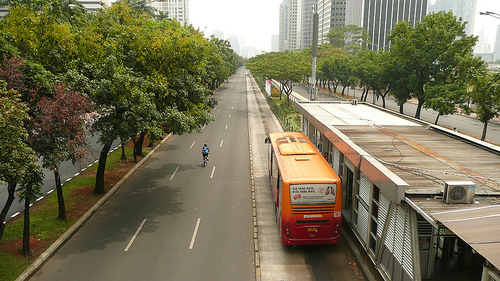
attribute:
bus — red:
[262, 127, 347, 252]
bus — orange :
[216, 121, 400, 233]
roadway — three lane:
[20, 51, 255, 279]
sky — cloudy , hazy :
[190, 3, 280, 38]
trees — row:
[232, 8, 487, 103]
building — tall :
[277, 0, 297, 51]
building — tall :
[312, 0, 362, 47]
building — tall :
[362, 0, 428, 51]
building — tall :
[432, 0, 476, 45]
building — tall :
[295, 0, 313, 48]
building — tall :
[278, 0, 293, 51]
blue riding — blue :
[201, 147, 210, 155]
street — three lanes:
[40, 69, 262, 273]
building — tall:
[275, 0, 300, 55]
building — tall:
[294, 0, 317, 50]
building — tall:
[313, 0, 345, 47]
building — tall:
[341, 0, 428, 56]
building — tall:
[427, 0, 478, 53]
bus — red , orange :
[267, 162, 355, 258]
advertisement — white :
[287, 180, 337, 206]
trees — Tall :
[6, 3, 244, 270]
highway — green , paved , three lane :
[26, 64, 261, 279]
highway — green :
[0, 102, 129, 224]